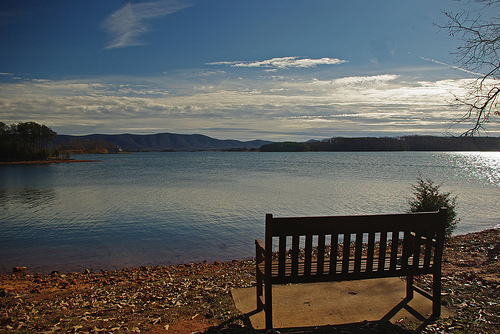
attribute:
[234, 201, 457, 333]
bench — wooden, empty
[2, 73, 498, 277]
view — peacful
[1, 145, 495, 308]
water — smooth, large, calm, sedate, serene, tranquil, mellow, untroubled, pacifying, amenable, mild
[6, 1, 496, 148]
sky — blue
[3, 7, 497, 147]
clouds — white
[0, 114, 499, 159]
mountains — short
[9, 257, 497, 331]
leaves — falling, dead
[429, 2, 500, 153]
tree — leafless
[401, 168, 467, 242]
tree — small, short, green, growing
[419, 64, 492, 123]
sun — hidden, shining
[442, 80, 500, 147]
branches — hanging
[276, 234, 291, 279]
slat — wooden